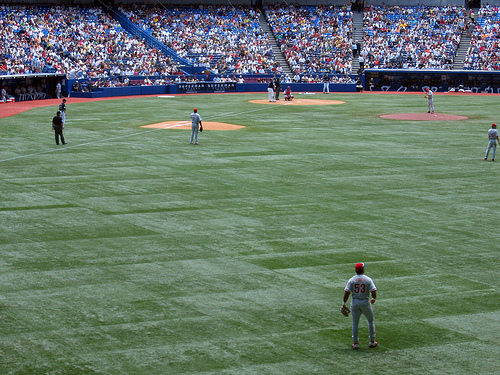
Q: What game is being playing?
A: Baseball.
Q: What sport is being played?
A: Baseball.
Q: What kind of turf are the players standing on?
A: Grass.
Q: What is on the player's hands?
A: Gloves.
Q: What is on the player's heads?
A: Hats.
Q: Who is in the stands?
A: Crowd.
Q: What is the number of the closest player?
A: 53.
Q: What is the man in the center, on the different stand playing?
A: Pitcher.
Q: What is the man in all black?
A: Umpire.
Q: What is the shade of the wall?
A: Blue.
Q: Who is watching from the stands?
A: A crowd of spectators.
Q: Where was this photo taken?
A: A baseball park.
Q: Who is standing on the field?
A: Baseball players and umpires.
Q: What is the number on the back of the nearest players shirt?
A: 53.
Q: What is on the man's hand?
A: The baseball player has a glove.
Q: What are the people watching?
A: The sport is baseball.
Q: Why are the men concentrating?
A: The players are alert.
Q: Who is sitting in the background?
A: There are many people in the stadium.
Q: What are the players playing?
A: This is major league baseball.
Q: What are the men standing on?
A: Patch of green baseball field.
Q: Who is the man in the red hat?
A: Baseball player on field.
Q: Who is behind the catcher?
A: Crowd at baseball game.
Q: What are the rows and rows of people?
A: Spectators at baseball game.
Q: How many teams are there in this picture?
A: Two.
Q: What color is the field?
A: Green.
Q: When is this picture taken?
A: Daytime.